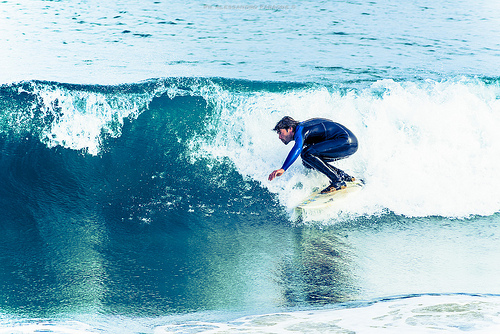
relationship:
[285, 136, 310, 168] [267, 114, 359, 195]
arm of person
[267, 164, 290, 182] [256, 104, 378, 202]
hand of person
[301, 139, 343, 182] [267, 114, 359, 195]
leg of person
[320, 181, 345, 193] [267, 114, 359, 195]
foot of person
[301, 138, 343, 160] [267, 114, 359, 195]
thigh of person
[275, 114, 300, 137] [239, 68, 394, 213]
hair of person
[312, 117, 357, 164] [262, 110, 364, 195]
body of person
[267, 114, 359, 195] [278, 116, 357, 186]
person in suit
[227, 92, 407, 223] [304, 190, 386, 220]
person balancing on surfboard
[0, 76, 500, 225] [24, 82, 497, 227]
wave at crest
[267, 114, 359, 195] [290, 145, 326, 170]
person has bent knees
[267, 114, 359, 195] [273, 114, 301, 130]
person has hair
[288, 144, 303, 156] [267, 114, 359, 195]
elbow of person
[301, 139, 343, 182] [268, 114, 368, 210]
leg of person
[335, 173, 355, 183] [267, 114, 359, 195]
foot of person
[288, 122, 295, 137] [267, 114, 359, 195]
ear of person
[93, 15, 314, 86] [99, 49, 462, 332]
body of water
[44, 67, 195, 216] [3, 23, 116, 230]
wave in ocean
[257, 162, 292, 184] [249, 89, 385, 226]
finger of a person